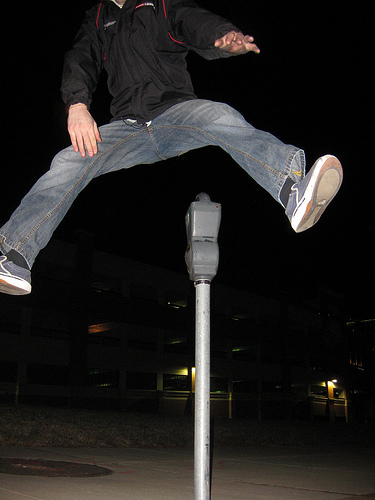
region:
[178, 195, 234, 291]
Parking meter is seen.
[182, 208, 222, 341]
Meter is grey color.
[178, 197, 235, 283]
Meter is grey color.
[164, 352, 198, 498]
lights are on due to dim light.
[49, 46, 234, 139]
one person is seen.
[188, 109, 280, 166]
man is wearing blue pant.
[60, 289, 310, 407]
night time picture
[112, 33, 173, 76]
Jacket is black color.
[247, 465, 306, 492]
Road is brown color.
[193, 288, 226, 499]
Pole is grey color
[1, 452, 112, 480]
a man hole cover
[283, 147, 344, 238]
a blue and white shoe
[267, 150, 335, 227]
black over the ankle socks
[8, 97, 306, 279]
a pair of blue jeans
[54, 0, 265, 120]
a black and red jacket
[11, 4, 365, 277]
a person wearing street clothes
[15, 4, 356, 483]
a person jumping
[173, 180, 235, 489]
a grey parking meter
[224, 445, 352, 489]
a pale cement sidewalk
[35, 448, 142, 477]
red graffiti on ground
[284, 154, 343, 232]
the man is wearing canvas slip on shoes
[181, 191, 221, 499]
the man is jumping over a parking meter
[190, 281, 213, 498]
the parking meter is on top of a metal pole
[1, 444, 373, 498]
there is a sidewalk behind the parking meter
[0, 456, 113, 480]
a manhole cover on the sidewalk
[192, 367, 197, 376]
a porchlight behind the parking meter is on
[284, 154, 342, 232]
the man's shoes are blue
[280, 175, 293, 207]
the man is wearing black socks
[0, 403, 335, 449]
there is a grass beyond the sidewalk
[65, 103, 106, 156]
one hand is near his thigh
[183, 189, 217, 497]
grey parking meter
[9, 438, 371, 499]
cement sidewalk around meter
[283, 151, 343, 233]
blue and white sneaker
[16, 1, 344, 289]
man jumping over meter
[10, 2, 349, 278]
man wearing blue jeans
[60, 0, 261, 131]
black and red jacket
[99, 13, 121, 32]
white lettering on black jacket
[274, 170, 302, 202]
black sock on left foot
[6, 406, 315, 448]
dead brown grass along sidewalk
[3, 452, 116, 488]
manhole cover in sidewalk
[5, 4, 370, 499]
the photo is clear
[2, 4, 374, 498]
the photo was taken outside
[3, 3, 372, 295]
a man is in the photo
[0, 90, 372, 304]
the man is wearing jeans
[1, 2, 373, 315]
the photo was taken at night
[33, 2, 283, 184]
the man is wearing a black coat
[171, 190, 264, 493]
the pole is grey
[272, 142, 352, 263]
the man is wearing jeans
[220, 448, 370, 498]
the floor is cemented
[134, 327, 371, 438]
light is in the photo